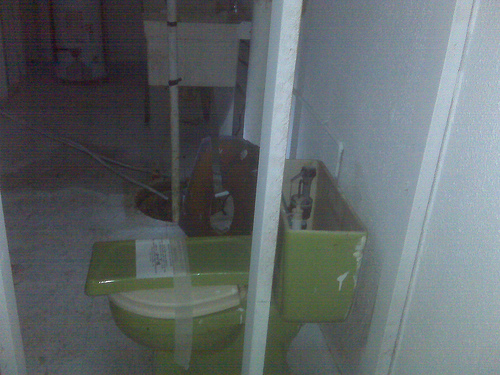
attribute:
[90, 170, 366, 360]
toilet — green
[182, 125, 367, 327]
tank — green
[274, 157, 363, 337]
tank cover — green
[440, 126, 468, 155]
ground — ivory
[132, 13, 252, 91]
sink — large, industrial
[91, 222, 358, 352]
toilet tank — Green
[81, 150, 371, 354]
toilet — green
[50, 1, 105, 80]
water heater — hot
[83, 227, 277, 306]
toilet lid — green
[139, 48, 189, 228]
pole — White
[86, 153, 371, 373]
toilet — green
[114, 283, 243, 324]
lid — white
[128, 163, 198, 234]
hole — open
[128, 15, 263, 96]
sink — white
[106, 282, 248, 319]
seat cover — beige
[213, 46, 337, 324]
post — white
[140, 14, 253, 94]
sink — slop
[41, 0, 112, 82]
water tank — White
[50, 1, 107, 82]
water tank — hot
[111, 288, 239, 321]
lid — closed, tan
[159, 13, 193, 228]
post — white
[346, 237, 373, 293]
paint — white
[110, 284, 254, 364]
toilet bowl — green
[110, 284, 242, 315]
seat — white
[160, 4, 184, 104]
electrical tape — black